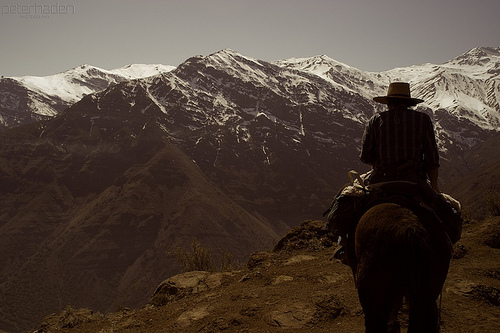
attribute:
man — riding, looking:
[348, 67, 453, 181]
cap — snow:
[372, 78, 424, 111]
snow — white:
[304, 44, 343, 63]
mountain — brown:
[243, 58, 341, 108]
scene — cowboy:
[239, 89, 475, 239]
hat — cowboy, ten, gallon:
[379, 73, 424, 101]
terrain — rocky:
[213, 245, 288, 277]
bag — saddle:
[310, 156, 376, 252]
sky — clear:
[140, 18, 178, 37]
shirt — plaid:
[359, 110, 446, 169]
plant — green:
[156, 252, 228, 281]